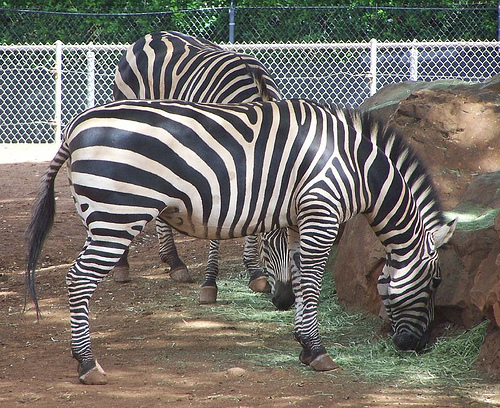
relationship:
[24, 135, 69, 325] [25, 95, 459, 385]
tail on zebra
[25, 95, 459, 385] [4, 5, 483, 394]
zebra grazing inside enclosure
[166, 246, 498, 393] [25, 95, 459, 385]
grass for zebra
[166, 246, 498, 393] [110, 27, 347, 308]
grass for zebra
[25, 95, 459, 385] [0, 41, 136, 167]
zebra in enclosure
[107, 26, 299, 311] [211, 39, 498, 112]
zebras in enclosure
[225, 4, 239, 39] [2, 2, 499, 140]
fencepost of fence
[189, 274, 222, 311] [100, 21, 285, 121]
brown hoof of zebra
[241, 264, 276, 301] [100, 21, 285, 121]
brown hoof of zebra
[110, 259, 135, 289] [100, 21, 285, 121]
brown hoof of zebra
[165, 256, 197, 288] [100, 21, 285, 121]
brown hoof of zebra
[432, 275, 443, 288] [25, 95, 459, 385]
eye of zebra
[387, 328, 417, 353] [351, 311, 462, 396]
mouth on grass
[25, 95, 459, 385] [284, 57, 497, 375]
zebra in front of rock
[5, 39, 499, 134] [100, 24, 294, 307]
fence behind zebra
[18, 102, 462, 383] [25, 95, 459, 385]
stripes on zebra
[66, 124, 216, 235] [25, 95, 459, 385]
stripe on a zebra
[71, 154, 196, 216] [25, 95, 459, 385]
stripe on a zebra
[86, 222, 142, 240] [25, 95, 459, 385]
stripe on a zebra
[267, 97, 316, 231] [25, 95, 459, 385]
stripe on a zebra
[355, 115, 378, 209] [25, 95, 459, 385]
stripe on a zebra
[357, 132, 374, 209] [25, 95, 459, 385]
stripe on a zebra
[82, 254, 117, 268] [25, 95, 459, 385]
stripe on a zebra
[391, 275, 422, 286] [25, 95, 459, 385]
stripe on a zebra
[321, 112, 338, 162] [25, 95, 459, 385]
stripe on a zebra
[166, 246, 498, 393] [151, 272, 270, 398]
grass on ground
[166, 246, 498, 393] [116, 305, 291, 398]
grass on ground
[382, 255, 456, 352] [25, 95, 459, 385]
face on zebra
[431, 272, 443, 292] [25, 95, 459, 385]
eye on zebra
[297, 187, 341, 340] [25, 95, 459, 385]
leg on zebra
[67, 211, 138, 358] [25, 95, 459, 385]
leg on zebra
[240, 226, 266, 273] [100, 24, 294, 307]
leg on zebra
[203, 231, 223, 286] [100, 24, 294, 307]
leg on zebra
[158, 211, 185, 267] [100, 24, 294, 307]
leg on zebra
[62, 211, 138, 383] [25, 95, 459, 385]
leg on zebra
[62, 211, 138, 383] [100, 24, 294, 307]
leg on zebra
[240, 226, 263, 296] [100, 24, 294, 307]
leg on zebra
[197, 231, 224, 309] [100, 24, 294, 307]
leg on zebra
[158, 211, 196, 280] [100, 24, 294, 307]
leg on zebra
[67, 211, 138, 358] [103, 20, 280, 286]
leg on zebra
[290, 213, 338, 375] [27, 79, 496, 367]
leg of zebra